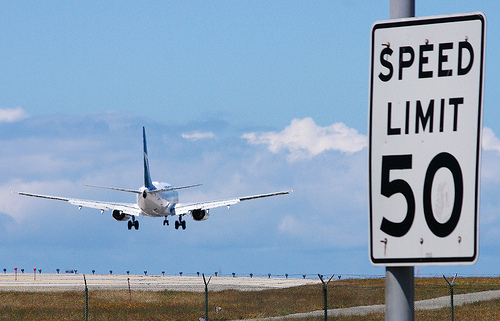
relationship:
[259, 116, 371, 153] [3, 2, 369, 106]
cloud in sky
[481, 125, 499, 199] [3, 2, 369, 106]
cloud on sky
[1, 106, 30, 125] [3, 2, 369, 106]
cloud in sky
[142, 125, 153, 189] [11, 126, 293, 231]
tail on plane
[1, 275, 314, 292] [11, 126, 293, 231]
runway under plane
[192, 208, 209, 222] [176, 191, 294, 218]
engine on wing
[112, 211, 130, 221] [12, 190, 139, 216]
engine on wing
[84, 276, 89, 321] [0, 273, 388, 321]
post for fence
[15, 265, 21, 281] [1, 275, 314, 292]
marker on runway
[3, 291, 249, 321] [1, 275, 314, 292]
grass by runway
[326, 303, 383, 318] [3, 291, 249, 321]
path by grass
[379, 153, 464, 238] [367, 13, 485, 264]
number on sign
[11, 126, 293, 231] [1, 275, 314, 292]
plane approaching runway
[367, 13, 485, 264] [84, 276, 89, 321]
sign on post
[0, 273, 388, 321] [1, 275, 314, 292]
fence near runway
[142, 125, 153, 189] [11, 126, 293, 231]
tail of airplane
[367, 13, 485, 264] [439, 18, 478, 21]
sign part black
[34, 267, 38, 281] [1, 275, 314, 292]
light on runway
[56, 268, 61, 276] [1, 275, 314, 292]
light on runway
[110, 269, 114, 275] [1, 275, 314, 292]
light on runway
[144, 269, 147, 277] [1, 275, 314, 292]
light on runway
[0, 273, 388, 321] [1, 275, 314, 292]
fence around runway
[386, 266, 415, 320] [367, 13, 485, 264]
pole of sign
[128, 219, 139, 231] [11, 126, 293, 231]
wheels on plane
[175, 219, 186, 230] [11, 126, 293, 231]
wheels on plane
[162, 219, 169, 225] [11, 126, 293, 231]
wheels of plane